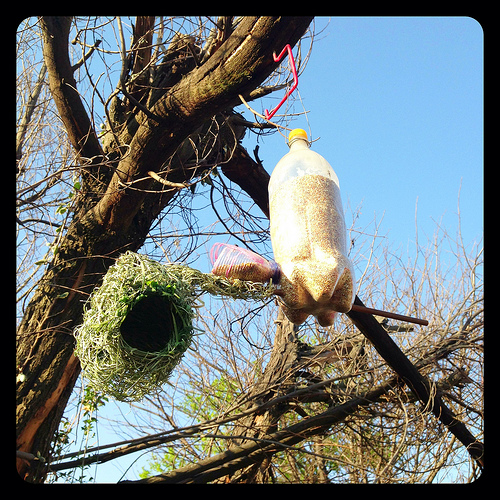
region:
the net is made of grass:
[92, 268, 189, 400]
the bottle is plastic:
[262, 132, 369, 302]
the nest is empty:
[85, 264, 200, 387]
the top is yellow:
[284, 123, 324, 142]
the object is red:
[257, 45, 308, 122]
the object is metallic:
[260, 48, 307, 116]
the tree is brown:
[20, 309, 69, 429]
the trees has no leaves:
[305, 374, 458, 472]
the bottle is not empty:
[264, 147, 360, 292]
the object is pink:
[205, 238, 270, 281]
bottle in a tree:
[257, 121, 365, 297]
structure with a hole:
[80, 270, 206, 387]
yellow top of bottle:
[270, 116, 330, 156]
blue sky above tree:
[346, 50, 441, 132]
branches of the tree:
[25, 31, 230, 163]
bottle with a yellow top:
[230, 97, 388, 312]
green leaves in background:
[199, 383, 251, 424]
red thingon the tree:
[233, 48, 320, 129]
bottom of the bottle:
[279, 246, 366, 330]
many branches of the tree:
[389, 218, 475, 294]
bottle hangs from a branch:
[254, 116, 366, 333]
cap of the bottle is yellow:
[279, 123, 312, 146]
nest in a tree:
[70, 243, 208, 409]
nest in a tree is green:
[60, 235, 203, 425]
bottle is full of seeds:
[247, 115, 365, 330]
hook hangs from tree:
[252, 38, 307, 128]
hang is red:
[250, 36, 310, 126]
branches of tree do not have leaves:
[2, 2, 323, 157]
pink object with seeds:
[192, 220, 277, 291]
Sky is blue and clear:
[332, 25, 473, 168]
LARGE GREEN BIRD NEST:
[78, 242, 196, 394]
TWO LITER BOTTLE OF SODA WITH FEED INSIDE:
[271, 100, 361, 320]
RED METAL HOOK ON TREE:
[256, 46, 291, 106]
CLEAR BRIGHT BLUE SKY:
[321, 30, 466, 236]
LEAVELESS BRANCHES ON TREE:
[230, 327, 443, 477]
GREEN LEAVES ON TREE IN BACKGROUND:
[185, 382, 398, 477]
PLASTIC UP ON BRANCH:
[200, 243, 290, 284]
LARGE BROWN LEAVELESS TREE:
[62, 60, 207, 377]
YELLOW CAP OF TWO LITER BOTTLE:
[287, 121, 303, 136]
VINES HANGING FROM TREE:
[66, 379, 109, 486]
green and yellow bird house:
[73, 250, 197, 404]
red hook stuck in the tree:
[254, 44, 310, 121]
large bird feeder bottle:
[211, 125, 361, 329]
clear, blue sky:
[346, 16, 483, 222]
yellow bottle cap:
[280, 122, 315, 147]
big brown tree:
[16, 7, 317, 480]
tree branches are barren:
[199, 227, 482, 497]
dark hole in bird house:
[124, 291, 176, 353]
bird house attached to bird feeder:
[56, 127, 440, 403]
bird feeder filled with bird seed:
[211, 122, 361, 329]